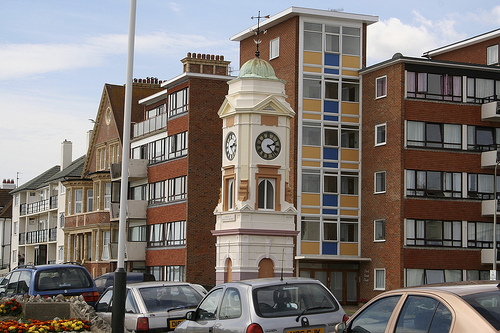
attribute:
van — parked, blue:
[0, 263, 101, 311]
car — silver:
[170, 275, 351, 332]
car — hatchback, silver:
[90, 279, 208, 332]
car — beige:
[332, 279, 499, 332]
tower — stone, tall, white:
[211, 10, 300, 284]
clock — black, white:
[254, 129, 282, 161]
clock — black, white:
[223, 131, 238, 161]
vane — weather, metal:
[248, 8, 271, 58]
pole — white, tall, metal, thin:
[114, 0, 137, 270]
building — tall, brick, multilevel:
[109, 7, 500, 313]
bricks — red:
[190, 83, 213, 280]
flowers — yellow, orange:
[0, 316, 96, 332]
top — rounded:
[233, 56, 277, 79]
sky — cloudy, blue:
[0, 1, 499, 188]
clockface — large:
[255, 130, 281, 159]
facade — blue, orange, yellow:
[300, 50, 363, 258]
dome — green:
[238, 59, 280, 79]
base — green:
[111, 266, 128, 332]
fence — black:
[17, 227, 57, 243]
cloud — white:
[2, 31, 230, 79]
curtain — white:
[305, 23, 321, 52]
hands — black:
[268, 139, 278, 153]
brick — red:
[285, 24, 296, 43]